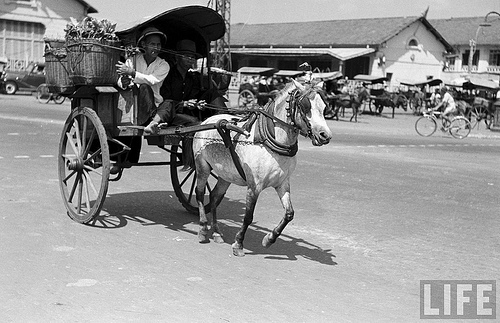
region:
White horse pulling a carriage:
[190, 77, 330, 253]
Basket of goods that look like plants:
[65, 10, 120, 85]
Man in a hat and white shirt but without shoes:
[115, 20, 170, 130]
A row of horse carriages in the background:
[230, 65, 495, 115]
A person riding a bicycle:
[410, 85, 470, 135]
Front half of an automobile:
[0, 55, 40, 90]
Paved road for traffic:
[0, 101, 495, 316]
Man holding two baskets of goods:
[40, 16, 170, 131]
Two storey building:
[195, 10, 450, 105]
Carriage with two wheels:
[55, 5, 230, 222]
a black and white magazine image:
[2, 0, 497, 318]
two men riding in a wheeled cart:
[55, 0, 227, 220]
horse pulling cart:
[52, 1, 327, 256]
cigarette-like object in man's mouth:
[137, 32, 162, 57]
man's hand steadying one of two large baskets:
[40, 15, 166, 97]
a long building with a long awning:
[222, 15, 449, 86]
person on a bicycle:
[411, 82, 471, 137]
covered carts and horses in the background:
[232, 65, 492, 130]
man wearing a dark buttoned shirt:
[159, 45, 200, 102]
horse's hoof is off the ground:
[257, 225, 297, 262]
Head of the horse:
[285, 73, 335, 160]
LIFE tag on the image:
[410, 270, 498, 321]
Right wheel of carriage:
[40, 99, 121, 235]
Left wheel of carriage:
[163, 118, 235, 221]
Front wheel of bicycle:
[408, 109, 441, 142]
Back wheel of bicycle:
[447, 112, 473, 142]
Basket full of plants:
[58, 11, 130, 89]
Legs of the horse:
[178, 156, 300, 256]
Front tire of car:
[1, 79, 19, 97]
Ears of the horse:
[284, 69, 331, 96]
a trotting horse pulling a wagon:
[191, 77, 326, 254]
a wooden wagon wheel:
[55, 106, 110, 223]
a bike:
[413, 109, 471, 139]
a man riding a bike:
[432, 86, 458, 128]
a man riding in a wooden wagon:
[116, 24, 176, 134]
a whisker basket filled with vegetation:
[60, 15, 122, 80]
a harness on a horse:
[175, 110, 294, 175]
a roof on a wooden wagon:
[110, 3, 227, 43]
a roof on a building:
[210, 15, 462, 47]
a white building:
[361, 13, 449, 86]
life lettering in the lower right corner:
[418, 280, 493, 315]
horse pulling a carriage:
[44, 3, 331, 258]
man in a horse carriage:
[119, 28, 172, 135]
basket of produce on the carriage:
[44, 21, 118, 93]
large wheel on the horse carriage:
[61, 106, 112, 222]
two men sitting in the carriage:
[114, 26, 200, 131]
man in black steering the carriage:
[168, 37, 208, 105]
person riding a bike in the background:
[412, 85, 473, 135]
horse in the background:
[329, 86, 369, 124]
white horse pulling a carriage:
[191, 79, 331, 266]